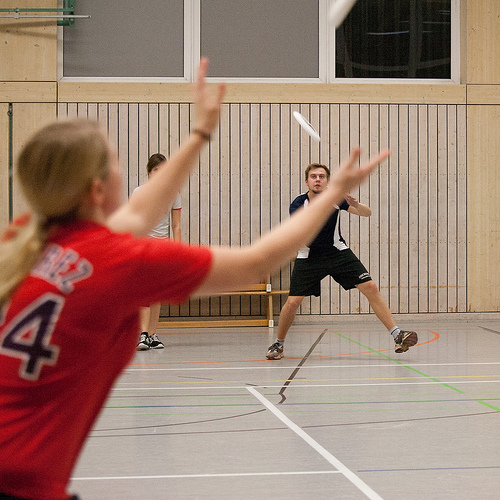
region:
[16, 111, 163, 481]
this is a woman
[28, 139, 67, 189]
the hair is blonde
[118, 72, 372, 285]
the woman's arms are raised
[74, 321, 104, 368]
the t-shirt is red in color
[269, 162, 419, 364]
this is a man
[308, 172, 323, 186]
the man is looking at something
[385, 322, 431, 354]
the man's foot is raised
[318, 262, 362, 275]
the shorts are black in color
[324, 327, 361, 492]
this is the floor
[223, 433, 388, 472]
the floor is slippery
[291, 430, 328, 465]
part of a white line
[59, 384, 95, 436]
part of a red top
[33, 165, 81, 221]
part of a lady's hair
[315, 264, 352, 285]
part of a black short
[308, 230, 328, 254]
part of a dark top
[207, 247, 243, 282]
part of a bicep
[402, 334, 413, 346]
sole of a shoe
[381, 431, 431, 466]
part of the floor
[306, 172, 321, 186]
face of a man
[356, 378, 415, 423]
part of the floor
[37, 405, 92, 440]
part of a red top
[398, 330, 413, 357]
sole of a shoe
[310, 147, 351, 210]
part of a right hand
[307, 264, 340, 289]
part of a short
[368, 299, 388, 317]
part of the left leg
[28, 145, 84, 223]
hair of a lady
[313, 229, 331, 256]
part of a black top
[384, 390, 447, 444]
par of the ground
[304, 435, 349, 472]
part of a white line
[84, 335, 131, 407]
part of a red top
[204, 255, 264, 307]
part of a bicep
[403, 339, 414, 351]
sole of a shoe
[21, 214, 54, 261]
hair of a lady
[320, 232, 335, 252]
part of a black top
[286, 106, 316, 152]
part of a white dish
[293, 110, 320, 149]
it is a white frisbee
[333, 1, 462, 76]
a window up above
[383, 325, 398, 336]
the man is wearing white socks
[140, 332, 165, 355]
the person is wearing black shoes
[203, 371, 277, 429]
a grey basketball court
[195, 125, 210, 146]
person is wearing a wrist band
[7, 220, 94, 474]
girl is wearing a red jersey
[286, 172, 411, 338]
man dressed in black shirt playing frisbee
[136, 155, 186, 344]
girl in white shirt in the background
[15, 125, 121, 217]
the woman has blonde hair